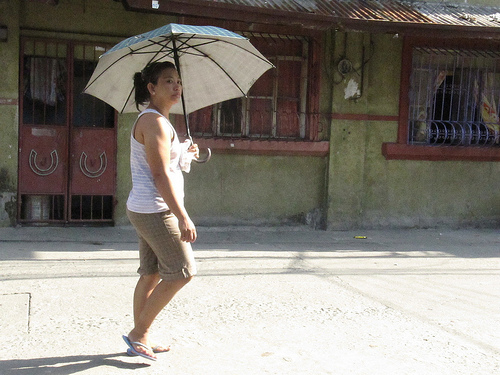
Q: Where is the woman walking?
A: Down the street.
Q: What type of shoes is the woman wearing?
A: Flip flops.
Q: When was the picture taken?
A: Daytime.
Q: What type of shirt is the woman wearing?
A: A tank top.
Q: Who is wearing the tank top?
A: The lady.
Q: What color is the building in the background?
A: Green.